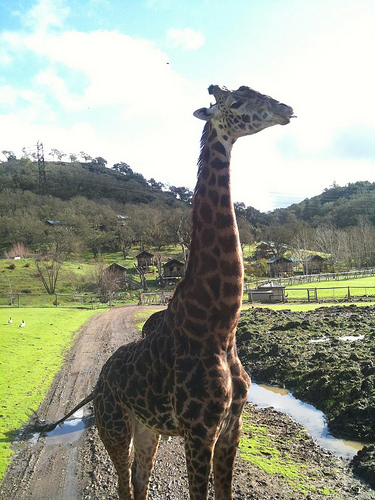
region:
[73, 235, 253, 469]
the giraffe has spots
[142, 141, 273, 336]
the giraffe has spots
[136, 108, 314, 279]
the giraffe has spots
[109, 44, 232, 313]
the giraffe has spots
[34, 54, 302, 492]
Giraffe standing on dirt road.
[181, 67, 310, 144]
Giraffe sticking out tongue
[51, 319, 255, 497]
Dirt road in field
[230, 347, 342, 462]
Water on side of road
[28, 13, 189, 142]
White cloud in the sky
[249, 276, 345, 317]
Fence in background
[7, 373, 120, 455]
Tail of a giraffe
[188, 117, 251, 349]
Long neck of a giraffe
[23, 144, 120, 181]
Trees on a distant hill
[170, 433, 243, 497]
Front legs of a giraffe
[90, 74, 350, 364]
the giraffe has stripes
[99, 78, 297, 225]
the giraffe has stripes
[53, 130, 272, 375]
the giraffe has stripes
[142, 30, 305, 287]
the giraffe has stripes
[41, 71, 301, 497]
brown and tan spotted standing giraffe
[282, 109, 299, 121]
outstretched giraffe tongue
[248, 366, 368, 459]
small stream of water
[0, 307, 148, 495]
brown muddy path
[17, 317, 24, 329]
duck sitting in the grass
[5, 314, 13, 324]
duck sitting in the grass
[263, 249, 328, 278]
building in the distance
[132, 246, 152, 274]
building in the distance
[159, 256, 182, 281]
building in the distance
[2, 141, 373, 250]
tree lined hillside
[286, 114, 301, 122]
Giraffe tongue sticking out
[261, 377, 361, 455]
Puddle of water in the mud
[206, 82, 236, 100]
Horns on a giraffe's head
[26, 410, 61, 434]
Hairs on a giraffe's tail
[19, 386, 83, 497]
Vehicle tracks in the mud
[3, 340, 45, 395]
Grass in a field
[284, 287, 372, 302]
Fence in an animals pen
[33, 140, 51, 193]
Metal utility pole in a hill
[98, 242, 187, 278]
Buildings behind a giraffe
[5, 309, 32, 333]
White animals in the grass